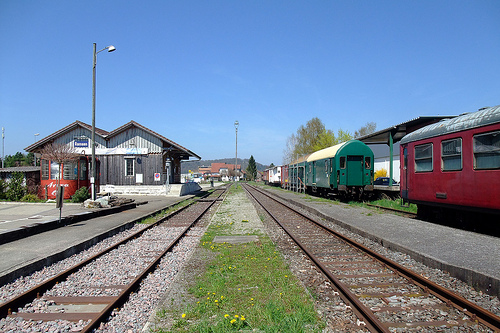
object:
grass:
[168, 235, 322, 331]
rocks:
[20, 258, 81, 277]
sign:
[55, 184, 64, 209]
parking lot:
[1, 201, 88, 240]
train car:
[287, 140, 387, 203]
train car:
[393, 106, 498, 227]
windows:
[470, 129, 500, 170]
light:
[90, 40, 118, 202]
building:
[23, 119, 201, 186]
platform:
[32, 157, 222, 197]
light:
[232, 119, 239, 192]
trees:
[281, 117, 337, 166]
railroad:
[9, 144, 498, 332]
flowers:
[223, 312, 250, 327]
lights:
[0, 127, 6, 168]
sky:
[2, 1, 493, 145]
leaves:
[312, 135, 325, 144]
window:
[125, 158, 133, 176]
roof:
[23, 117, 200, 160]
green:
[301, 132, 312, 138]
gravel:
[90, 258, 140, 278]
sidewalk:
[1, 195, 184, 300]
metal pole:
[91, 41, 98, 203]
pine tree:
[246, 155, 258, 181]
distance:
[197, 156, 276, 186]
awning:
[348, 115, 450, 145]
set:
[105, 218, 423, 333]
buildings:
[199, 162, 247, 182]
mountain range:
[182, 157, 270, 174]